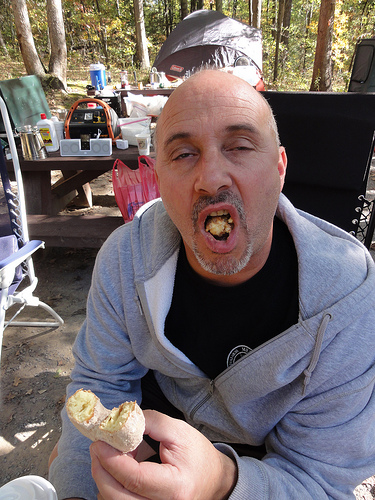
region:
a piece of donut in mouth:
[206, 215, 232, 240]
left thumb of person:
[143, 411, 200, 449]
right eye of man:
[166, 144, 200, 168]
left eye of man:
[221, 132, 261, 154]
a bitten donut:
[67, 374, 147, 452]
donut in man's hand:
[69, 373, 158, 458]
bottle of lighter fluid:
[34, 109, 61, 158]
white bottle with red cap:
[33, 111, 65, 150]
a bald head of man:
[149, 59, 270, 131]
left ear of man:
[271, 143, 291, 193]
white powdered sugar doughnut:
[62, 383, 142, 449]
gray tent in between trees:
[142, 3, 262, 94]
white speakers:
[55, 136, 117, 158]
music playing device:
[75, 124, 93, 149]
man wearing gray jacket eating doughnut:
[39, 64, 373, 498]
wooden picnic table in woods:
[0, 108, 223, 271]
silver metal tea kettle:
[11, 121, 52, 163]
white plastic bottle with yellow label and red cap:
[32, 110, 58, 153]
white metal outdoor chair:
[0, 88, 66, 372]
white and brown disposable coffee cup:
[134, 132, 153, 158]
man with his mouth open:
[57, 64, 373, 497]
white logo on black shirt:
[218, 341, 252, 364]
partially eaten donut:
[61, 384, 162, 446]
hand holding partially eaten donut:
[91, 406, 220, 499]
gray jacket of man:
[54, 203, 371, 491]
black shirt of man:
[160, 246, 303, 378]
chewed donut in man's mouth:
[201, 217, 231, 237]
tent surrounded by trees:
[143, 2, 266, 80]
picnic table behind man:
[1, 117, 190, 243]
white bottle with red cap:
[27, 108, 54, 146]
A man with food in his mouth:
[136, 61, 294, 281]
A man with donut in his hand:
[54, 388, 199, 476]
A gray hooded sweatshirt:
[96, 227, 359, 448]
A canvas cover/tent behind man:
[158, 9, 268, 74]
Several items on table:
[18, 86, 148, 158]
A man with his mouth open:
[147, 52, 289, 260]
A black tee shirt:
[177, 268, 262, 348]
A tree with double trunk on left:
[7, 2, 75, 67]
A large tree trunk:
[304, 2, 337, 89]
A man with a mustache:
[156, 58, 279, 296]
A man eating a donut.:
[48, 69, 374, 499]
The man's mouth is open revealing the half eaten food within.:
[195, 203, 241, 253]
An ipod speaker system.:
[58, 138, 111, 155]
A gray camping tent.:
[150, 9, 263, 89]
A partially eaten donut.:
[65, 388, 145, 452]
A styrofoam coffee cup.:
[135, 133, 150, 155]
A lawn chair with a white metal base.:
[0, 96, 62, 345]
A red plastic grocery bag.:
[110, 154, 160, 222]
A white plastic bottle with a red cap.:
[36, 113, 58, 152]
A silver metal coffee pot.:
[15, 124, 49, 159]